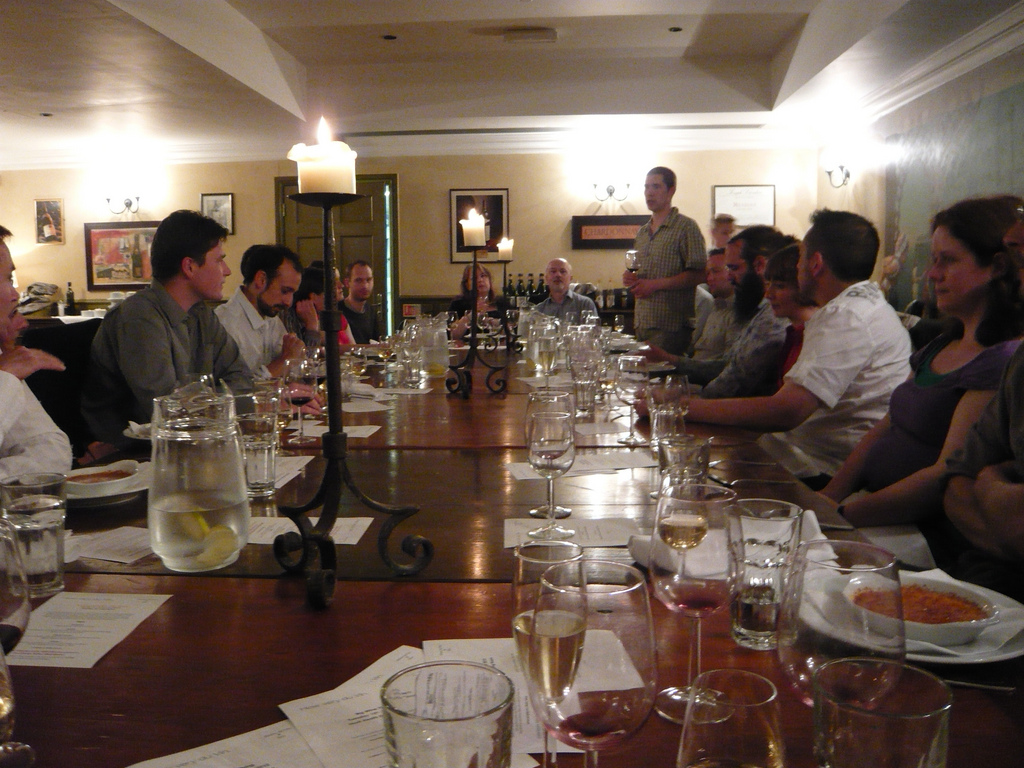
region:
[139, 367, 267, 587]
a pitcher of ice water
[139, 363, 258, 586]
A picture of ice water with lemons in it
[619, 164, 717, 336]
a man holding a beverage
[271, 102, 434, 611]
A candle burning on the table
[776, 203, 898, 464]
a Man wearing a white short-sleeved shirt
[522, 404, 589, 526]
a glass for ice water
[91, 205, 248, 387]
a man wearing a casual shirt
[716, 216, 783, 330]
A man sporting a beard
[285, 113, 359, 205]
The closest, lit candle on the table.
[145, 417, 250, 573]
Larger flask of lemon water.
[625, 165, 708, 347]
The man standing at the dinner table.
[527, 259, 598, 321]
Older gentleman at the head of the table.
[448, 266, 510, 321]
Woman sitting at the head of the table.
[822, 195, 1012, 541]
The woman on the right side in purple.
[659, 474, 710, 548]
Glass of champagne.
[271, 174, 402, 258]
Door in the background; entrance.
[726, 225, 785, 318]
The man on the right with the big beard.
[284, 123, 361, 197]
a short white candle is lit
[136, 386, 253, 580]
a clear glass pitcher of water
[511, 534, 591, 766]
the champagne flute is half full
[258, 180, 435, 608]
a tall metal candle holder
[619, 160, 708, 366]
a man is standing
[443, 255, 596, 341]
a man and woman are sitting at the end of the table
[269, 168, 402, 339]
the door is closed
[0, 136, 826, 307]
the back wall is a light tan color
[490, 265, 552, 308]
a row of wine bottles against the far wall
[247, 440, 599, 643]
The black man is eating.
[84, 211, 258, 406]
sitting man in gray shirt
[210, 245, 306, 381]
man with head bowed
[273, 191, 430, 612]
closest candle stick holder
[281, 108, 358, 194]
closest candle on candle stick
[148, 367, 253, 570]
water pitcher with lemon slices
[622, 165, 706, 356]
man standing up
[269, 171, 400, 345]
green door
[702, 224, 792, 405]
man with long beard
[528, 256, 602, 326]
man sitting at the table's end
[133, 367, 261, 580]
A pitcher of water with lemons in it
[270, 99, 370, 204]
A candle is lit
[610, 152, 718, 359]
A man is standing up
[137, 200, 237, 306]
Black hair on man's head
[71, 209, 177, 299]
A painting on the wall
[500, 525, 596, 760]
A glass of champagne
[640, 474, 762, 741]
A little wine in a glass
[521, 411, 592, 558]
A vessel made for drinking.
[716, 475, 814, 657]
A vessel made for drinking.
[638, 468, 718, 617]
A vessel made for drinking.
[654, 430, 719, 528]
A vessel made for drinking.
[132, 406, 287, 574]
A vessel made for drinking.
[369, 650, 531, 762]
A vessel made for drinking.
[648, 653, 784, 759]
A vessel made for drinking.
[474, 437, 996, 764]
a group of glasses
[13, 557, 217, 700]
paper on the table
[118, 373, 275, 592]
a glass water pitcher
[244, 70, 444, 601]
candle on a stand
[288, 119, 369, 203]
the candle is lit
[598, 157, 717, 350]
a man standing up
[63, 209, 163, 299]
picture on the wal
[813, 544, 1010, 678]
a bowl of food